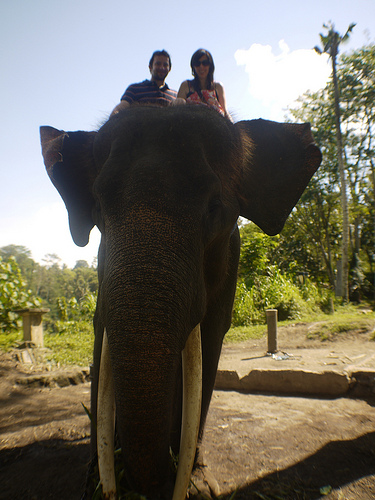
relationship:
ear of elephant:
[20, 122, 134, 235] [32, 114, 317, 402]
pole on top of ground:
[255, 306, 295, 363] [303, 339, 345, 363]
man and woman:
[109, 48, 185, 119] [178, 35, 221, 97]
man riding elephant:
[109, 48, 185, 119] [19, 54, 308, 489]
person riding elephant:
[175, 47, 232, 123] [19, 54, 308, 489]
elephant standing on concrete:
[40, 100, 322, 499] [1, 368, 373, 498]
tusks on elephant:
[95, 319, 202, 499] [40, 100, 322, 499]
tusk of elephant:
[171, 321, 202, 498] [40, 100, 322, 499]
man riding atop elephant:
[109, 49, 185, 119] [40, 100, 322, 499]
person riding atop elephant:
[175, 47, 230, 124] [40, 100, 322, 499]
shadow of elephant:
[3, 430, 373, 498] [40, 100, 322, 499]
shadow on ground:
[3, 430, 373, 498] [4, 329, 373, 498]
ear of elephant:
[236, 115, 318, 234] [203, 117, 317, 237]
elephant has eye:
[40, 100, 322, 499] [209, 194, 222, 213]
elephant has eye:
[40, 100, 322, 499] [93, 197, 103, 216]